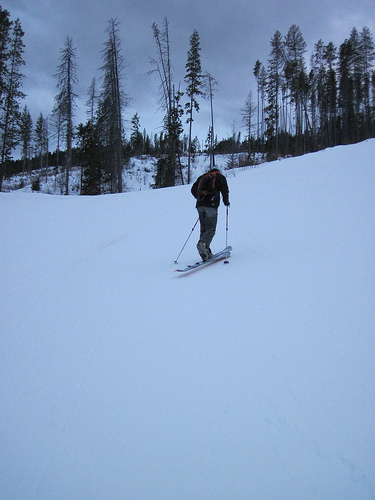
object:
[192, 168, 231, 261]
skier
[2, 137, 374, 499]
slope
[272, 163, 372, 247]
snow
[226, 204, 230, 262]
ski pole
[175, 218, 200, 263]
ski pole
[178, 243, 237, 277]
skies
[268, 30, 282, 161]
trees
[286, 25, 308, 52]
top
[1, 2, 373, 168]
sky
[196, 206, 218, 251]
pants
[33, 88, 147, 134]
cloud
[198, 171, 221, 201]
backpack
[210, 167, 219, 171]
helmet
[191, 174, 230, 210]
jacket